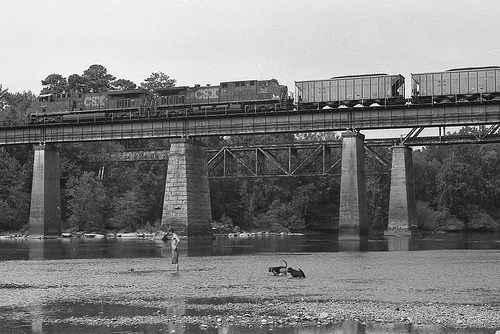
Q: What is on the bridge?
A: A train.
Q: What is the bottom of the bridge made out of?
A: Stones.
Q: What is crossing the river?
A: A train.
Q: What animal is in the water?
A: Dogs.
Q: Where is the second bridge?
A: On the other side of the first bridge.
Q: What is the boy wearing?
A: Short.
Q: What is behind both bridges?
A: Trees.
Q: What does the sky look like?
A: Clear.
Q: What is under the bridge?
A: Water.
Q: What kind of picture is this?
A: Black and white.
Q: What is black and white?
A: The photo is black and white.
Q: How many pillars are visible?
A: 4.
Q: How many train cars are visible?
A: 4.